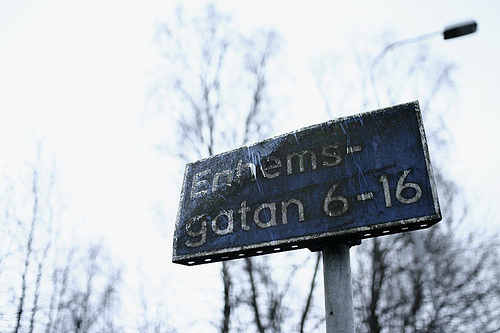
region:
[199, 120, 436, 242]
sign on a pole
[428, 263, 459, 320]
branch on the tree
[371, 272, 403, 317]
branch on the tree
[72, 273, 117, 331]
branch on the tree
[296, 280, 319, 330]
branch on the tree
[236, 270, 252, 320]
branch on the tree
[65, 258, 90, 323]
branch on the tree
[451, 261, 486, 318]
branch on the tree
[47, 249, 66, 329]
branch on the tree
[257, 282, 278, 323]
branch on the tree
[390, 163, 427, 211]
white letter on a sign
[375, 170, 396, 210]
white letter on a sign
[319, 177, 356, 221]
white letter on a sign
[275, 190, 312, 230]
white letter on a sign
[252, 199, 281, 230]
white letter on a sign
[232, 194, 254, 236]
white letter on a sign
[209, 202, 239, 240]
white letter on a sign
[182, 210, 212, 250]
white letter on a sign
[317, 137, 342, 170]
white letter on a sign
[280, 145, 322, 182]
white letter on a sign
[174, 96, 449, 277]
blue and white sign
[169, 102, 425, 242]
blue rectangular sign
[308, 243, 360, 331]
silver post of sign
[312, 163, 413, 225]
white numbers on sign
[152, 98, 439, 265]
blue and white street sign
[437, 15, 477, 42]
street light in sky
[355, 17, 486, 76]
street light attached to pole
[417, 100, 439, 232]
white boarder of blue sign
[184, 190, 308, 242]
white words written on sign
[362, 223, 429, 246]
white bolts on bottom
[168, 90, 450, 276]
direction sign with the letter e on it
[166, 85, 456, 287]
direction sign with the letter n on it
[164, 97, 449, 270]
direction sign with the letter h on it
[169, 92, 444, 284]
direction sign with the letter m on it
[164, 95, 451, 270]
direction sign with the letter s on it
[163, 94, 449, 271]
direction sign with the letter g on it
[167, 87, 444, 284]
direction sign with the letter a on it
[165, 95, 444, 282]
direction sign with the letter t on it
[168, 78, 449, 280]
direction sign with the number 6 on it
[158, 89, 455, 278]
direction sign with the number 1 on it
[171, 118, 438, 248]
road sign on pole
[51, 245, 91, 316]
branches of the tree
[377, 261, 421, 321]
branches of the tree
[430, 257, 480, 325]
branches of the tree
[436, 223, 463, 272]
branches of the tree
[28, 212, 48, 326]
branches of the tree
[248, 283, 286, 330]
branches of the tree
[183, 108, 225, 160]
branches of the tree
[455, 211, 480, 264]
branches of the tree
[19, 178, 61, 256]
branches of the tree